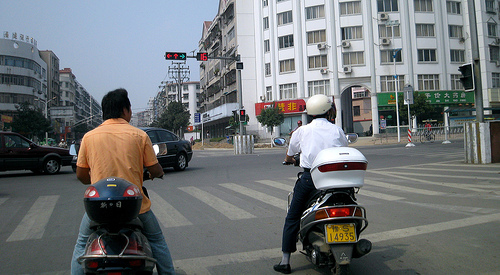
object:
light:
[457, 63, 475, 91]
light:
[166, 52, 187, 60]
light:
[197, 53, 210, 61]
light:
[239, 109, 247, 123]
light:
[235, 62, 244, 71]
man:
[67, 86, 177, 275]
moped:
[75, 225, 168, 275]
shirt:
[71, 120, 162, 217]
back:
[85, 228, 153, 275]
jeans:
[62, 208, 183, 275]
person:
[268, 89, 377, 274]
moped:
[288, 186, 382, 274]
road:
[0, 139, 500, 275]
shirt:
[285, 116, 355, 172]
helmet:
[303, 93, 337, 116]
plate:
[322, 221, 360, 244]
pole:
[233, 55, 248, 135]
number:
[199, 52, 209, 62]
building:
[188, 0, 500, 145]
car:
[0, 130, 72, 177]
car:
[67, 124, 201, 178]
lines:
[8, 208, 500, 275]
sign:
[375, 88, 478, 106]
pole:
[466, 0, 486, 121]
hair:
[96, 87, 135, 122]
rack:
[410, 125, 464, 137]